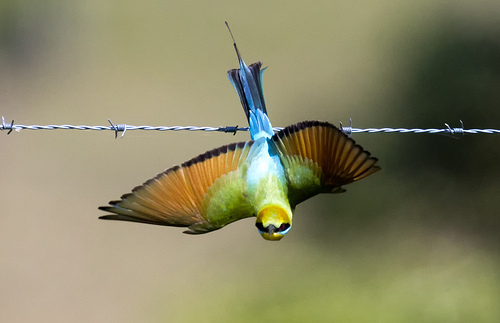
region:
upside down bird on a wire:
[97, 17, 379, 244]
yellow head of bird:
[254, 207, 291, 241]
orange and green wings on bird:
[100, 120, 385, 233]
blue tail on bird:
[224, 21, 276, 138]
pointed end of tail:
[221, 18, 246, 66]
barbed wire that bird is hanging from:
[1, 115, 498, 137]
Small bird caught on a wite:
[100, 35, 393, 263]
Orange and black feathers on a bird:
[113, 182, 150, 223]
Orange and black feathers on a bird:
[136, 174, 184, 226]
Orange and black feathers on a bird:
[158, 153, 192, 208]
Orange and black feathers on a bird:
[189, 149, 208, 188]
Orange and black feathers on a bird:
[210, 141, 231, 170]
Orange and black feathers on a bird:
[278, 124, 301, 158]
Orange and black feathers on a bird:
[300, 112, 318, 165]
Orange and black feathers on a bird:
[318, 116, 336, 168]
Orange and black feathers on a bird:
[343, 132, 378, 184]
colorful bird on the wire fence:
[101, 61, 381, 242]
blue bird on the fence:
[94, 50, 384, 242]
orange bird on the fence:
[84, 52, 380, 239]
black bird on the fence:
[94, 57, 383, 247]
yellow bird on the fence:
[97, 43, 381, 251]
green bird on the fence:
[92, 55, 380, 244]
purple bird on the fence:
[90, 54, 382, 249]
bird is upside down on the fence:
[92, 56, 384, 241]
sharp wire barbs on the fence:
[1, 112, 493, 139]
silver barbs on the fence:
[3, 108, 497, 147]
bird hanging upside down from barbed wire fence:
[16, 12, 486, 312]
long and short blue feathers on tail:
[222, 15, 272, 137]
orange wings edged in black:
[106, 118, 385, 235]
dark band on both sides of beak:
[255, 217, 291, 239]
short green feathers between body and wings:
[204, 155, 319, 217]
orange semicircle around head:
[253, 203, 292, 228]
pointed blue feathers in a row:
[248, 105, 275, 137]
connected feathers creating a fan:
[94, 141, 249, 234]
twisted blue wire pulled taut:
[8, 118, 495, 138]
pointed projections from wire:
[105, 115, 127, 140]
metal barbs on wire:
[104, 119, 134, 137]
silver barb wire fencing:
[0, 116, 215, 136]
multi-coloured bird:
[95, 40, 375, 273]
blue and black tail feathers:
[209, 19, 281, 111]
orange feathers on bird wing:
[157, 177, 199, 222]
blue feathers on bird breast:
[244, 137, 280, 179]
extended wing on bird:
[88, 125, 250, 251]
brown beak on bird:
[265, 220, 276, 236]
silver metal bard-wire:
[350, 121, 443, 137]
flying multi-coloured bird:
[36, 18, 416, 270]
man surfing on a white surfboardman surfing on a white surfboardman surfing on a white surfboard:
[296, 300, 335, 315]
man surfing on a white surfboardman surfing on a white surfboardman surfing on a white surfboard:
[344, 260, 360, 276]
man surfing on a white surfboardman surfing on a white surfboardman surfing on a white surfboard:
[330, 262, 360, 289]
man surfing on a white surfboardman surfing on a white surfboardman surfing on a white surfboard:
[300, 262, 329, 302]